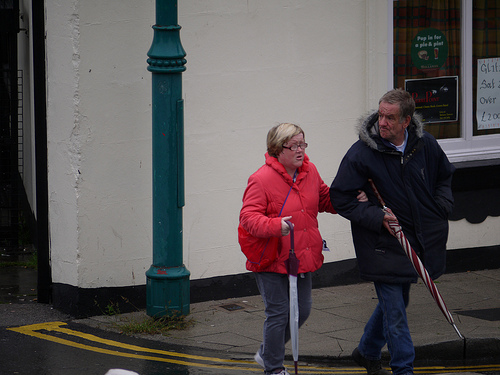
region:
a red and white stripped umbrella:
[368, 185, 469, 341]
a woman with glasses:
[262, 125, 315, 167]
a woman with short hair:
[259, 122, 314, 172]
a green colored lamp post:
[134, 20, 197, 315]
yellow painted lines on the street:
[20, 313, 107, 363]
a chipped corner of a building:
[59, 42, 90, 250]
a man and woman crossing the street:
[212, 93, 474, 358]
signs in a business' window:
[400, 17, 474, 125]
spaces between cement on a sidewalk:
[320, 298, 351, 333]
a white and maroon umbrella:
[273, 221, 317, 363]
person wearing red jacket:
[253, 161, 334, 269]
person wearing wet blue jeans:
[256, 271, 317, 373]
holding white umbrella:
[285, 223, 304, 373]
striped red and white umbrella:
[383, 182, 470, 335]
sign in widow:
[403, 75, 468, 125]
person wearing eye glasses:
[270, 129, 320, 176]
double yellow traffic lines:
[17, 320, 231, 374]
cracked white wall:
[63, 19, 98, 206]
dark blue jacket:
[343, 128, 470, 287]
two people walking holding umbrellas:
[238, 103, 497, 373]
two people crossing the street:
[231, 85, 468, 373]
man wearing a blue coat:
[336, 83, 480, 373]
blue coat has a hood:
[328, 103, 460, 287]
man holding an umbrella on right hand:
[330, 88, 472, 368]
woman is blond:
[247, 118, 327, 195]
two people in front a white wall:
[17, 2, 491, 348]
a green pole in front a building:
[137, 3, 198, 325]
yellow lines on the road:
[13, 308, 477, 374]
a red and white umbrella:
[356, 172, 471, 347]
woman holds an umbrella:
[229, 113, 341, 373]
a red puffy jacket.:
[234, 146, 361, 278]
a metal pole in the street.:
[137, 0, 199, 329]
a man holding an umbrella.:
[350, 172, 469, 351]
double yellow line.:
[11, 300, 331, 374]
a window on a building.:
[393, 0, 469, 162]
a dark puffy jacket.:
[321, 105, 480, 290]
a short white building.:
[9, 0, 498, 296]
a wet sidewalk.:
[56, 254, 498, 374]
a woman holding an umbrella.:
[269, 223, 311, 374]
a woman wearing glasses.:
[261, 113, 320, 173]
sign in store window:
[477, 55, 499, 133]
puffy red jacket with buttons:
[238, 158, 331, 273]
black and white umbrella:
[282, 219, 306, 374]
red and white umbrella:
[369, 183, 480, 353]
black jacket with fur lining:
[333, 110, 468, 287]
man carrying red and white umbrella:
[328, 87, 445, 374]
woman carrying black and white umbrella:
[238, 123, 320, 374]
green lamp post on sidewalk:
[138, 0, 196, 322]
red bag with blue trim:
[234, 165, 301, 270]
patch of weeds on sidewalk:
[99, 297, 199, 339]